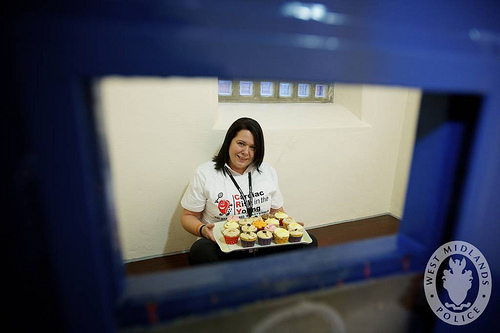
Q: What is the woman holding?
A: A tray.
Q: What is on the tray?
A: Cupcakes.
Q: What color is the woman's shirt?
A: White.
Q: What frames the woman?
A: A blue window.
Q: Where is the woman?
A: In a prison.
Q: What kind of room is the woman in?
A: A jail cell.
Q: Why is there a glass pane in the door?
A: To see through.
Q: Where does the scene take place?
A: Inside a prison.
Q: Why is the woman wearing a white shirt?
A: It is part of her uniform.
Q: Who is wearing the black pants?
A: The woman.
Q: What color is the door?
A: Blues.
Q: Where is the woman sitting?
A: Below a multi-paned window.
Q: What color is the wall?
A: White.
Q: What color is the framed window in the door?
A: Blue.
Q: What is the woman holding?
A: A tray.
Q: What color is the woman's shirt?
A: White with black writing.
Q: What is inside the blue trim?
A: A glass window.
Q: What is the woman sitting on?
A: A brown bench.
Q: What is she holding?
A: Cupcakes.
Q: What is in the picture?
A: Logo.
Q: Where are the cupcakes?
A: With the lady.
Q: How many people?
A: 1.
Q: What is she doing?
A: Smiling.